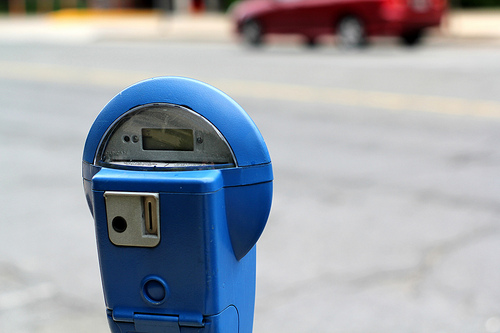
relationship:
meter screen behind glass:
[141, 125, 193, 152] [91, 103, 236, 168]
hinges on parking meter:
[110, 307, 204, 327] [82, 74, 274, 332]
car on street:
[231, 0, 445, 47] [1, 38, 500, 331]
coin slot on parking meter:
[141, 195, 158, 236] [82, 74, 274, 332]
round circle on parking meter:
[138, 275, 169, 308] [82, 74, 274, 332]